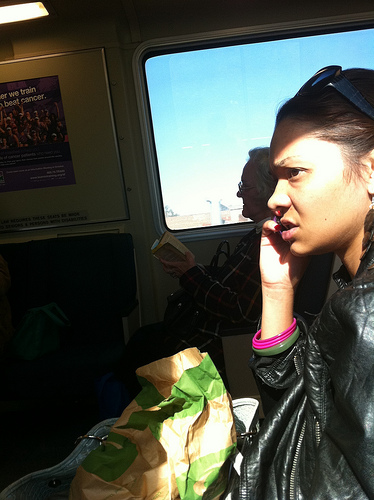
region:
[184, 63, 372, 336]
woman on the phone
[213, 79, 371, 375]
woman's face in the sun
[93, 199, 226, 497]
bag on woman's lap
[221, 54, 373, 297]
woman with sunglasses on head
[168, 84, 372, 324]
woman frowning on the phone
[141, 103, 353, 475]
woman wearing a black leather jacket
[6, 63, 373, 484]
people sitting on the train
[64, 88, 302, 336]
woman reading next to her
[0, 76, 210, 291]
advertisement on the train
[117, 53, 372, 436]
woman with pink bangles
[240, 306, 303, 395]
Pink and green bracelets.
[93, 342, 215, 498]
Tan and green bag.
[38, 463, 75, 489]
Silver clasp for a purse.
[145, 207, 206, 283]
Book being held in hand.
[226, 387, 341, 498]
Black jacket with zippers.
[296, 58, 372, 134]
Black sun glasses on head.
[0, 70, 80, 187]
Sign for beating cancer.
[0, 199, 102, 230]
A row of black words.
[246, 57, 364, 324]
Woman talking on a cellphone.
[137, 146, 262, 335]
Woman reading a book.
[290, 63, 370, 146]
the lady has sunglasses on top her head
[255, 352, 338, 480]
the lady is wearing a leather coat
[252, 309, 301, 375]
the lady has bracelets on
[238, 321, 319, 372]
the bracelets are green & purple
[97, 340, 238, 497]
the lady is holding a parcel in her lap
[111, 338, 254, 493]
the wrapper is green & brown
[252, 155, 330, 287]
the lady appears to be on a cell phone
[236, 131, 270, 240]
there is a man in the background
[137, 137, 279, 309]
the man is reading a book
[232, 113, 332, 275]
the girl looks upset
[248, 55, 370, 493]
a girl riding a train and taking on her cell phone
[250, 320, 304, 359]
pink and green plastic bracelets the girl is wearing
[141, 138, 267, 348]
an old lady reading a book next to the girl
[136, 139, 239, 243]
the edge of a window on the train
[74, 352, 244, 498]
a brown and green paper bag in the girl's lap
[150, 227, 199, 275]
a paperback book the old lady is reading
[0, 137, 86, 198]
a poster with an advertising on the wall of the train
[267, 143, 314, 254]
the girl has a look of concern on her face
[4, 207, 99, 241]
a white warning sign with black lettering on the wall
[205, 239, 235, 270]
the leather straps on the old lady's purse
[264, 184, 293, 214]
nose on a woman's face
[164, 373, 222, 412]
green on a paper sack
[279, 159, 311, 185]
eye on a woman's face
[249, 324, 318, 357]
bracelets on an arm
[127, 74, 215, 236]
window on a train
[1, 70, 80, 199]
sign on a the wall of train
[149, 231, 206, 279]
opened book in hands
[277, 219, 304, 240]
a mouth on a face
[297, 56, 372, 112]
sunglasses on a head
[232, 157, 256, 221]
profile of a mans face